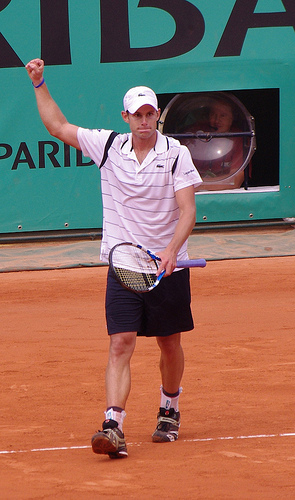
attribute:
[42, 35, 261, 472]
man — pictured, white-clothed, walking, sitting, wearing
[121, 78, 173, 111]
hat — white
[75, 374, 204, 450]
shoe — white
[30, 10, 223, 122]
wall — blue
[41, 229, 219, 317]
racket — tennis, blue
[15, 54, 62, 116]
bracelet — blue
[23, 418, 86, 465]
line — white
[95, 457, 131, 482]
dirt — tan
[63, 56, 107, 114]
cover — green